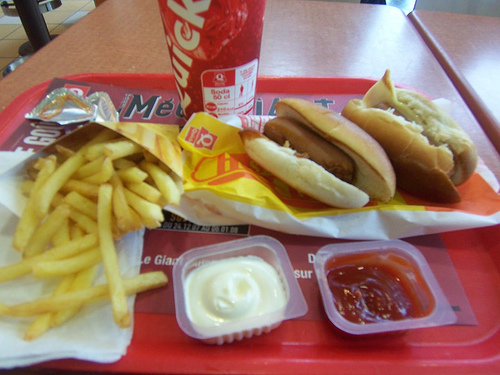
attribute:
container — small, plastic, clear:
[309, 235, 461, 340]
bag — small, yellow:
[1, 116, 181, 219]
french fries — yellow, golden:
[1, 107, 186, 346]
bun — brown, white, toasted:
[242, 95, 398, 211]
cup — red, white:
[154, 1, 268, 120]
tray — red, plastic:
[2, 69, 498, 374]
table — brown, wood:
[0, 1, 499, 199]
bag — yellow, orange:
[162, 109, 499, 241]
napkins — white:
[1, 146, 147, 371]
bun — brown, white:
[341, 67, 480, 206]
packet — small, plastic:
[167, 231, 313, 350]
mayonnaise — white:
[182, 254, 291, 329]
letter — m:
[119, 87, 162, 124]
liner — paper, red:
[2, 74, 481, 335]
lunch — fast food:
[3, 1, 481, 343]